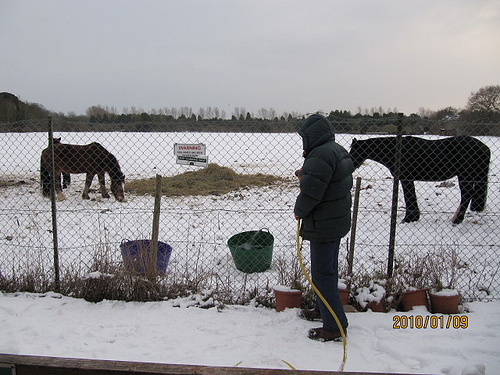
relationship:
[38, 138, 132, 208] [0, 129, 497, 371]
horse in snow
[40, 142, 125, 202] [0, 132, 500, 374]
horse in field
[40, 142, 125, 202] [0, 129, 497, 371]
horse in snow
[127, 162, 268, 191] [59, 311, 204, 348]
hay in snow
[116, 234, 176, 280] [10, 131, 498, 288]
bucket in field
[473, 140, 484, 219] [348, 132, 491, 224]
tail of horse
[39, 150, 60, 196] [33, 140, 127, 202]
tail of horse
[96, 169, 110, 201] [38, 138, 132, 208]
front leg of horse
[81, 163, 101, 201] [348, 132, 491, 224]
front leg of horse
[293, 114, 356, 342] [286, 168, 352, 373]
person with hose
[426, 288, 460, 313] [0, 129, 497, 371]
planting pot on snow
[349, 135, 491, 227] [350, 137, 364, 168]
horse has head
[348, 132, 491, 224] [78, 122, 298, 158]
horse in field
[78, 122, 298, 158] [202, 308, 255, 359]
field of snow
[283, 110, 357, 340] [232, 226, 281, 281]
person spraying water into bucket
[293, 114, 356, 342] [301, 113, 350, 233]
person in a jacket